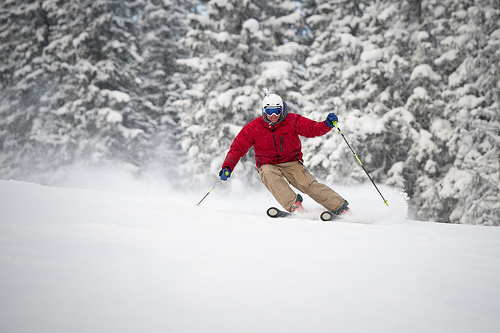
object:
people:
[194, 93, 407, 225]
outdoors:
[0, 0, 499, 331]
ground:
[16, 221, 468, 325]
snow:
[7, 236, 219, 324]